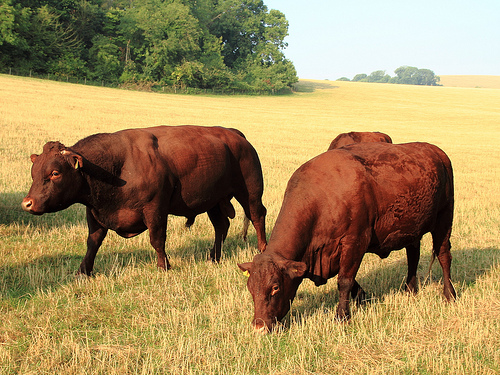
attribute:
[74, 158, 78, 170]
tag — yellow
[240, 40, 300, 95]
tree — green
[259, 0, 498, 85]
sky — blue 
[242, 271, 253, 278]
tag — Yellow 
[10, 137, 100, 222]
head — brown 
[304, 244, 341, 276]
brisket — long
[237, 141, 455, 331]
cow — brown 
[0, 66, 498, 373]
grass field — dry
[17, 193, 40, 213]
nose — tan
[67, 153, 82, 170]
cow ear — brown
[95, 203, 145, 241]
brisket — bulky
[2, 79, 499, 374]
golden grass — large 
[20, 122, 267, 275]
cow — brown 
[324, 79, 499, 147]
grass — brown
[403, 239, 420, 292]
leg — back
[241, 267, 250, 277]
tag — yellow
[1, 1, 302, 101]
trees — green